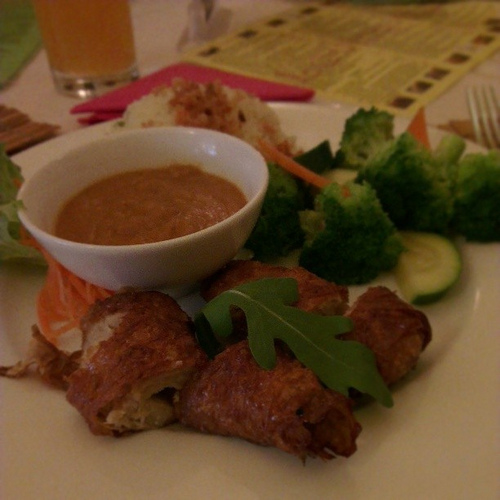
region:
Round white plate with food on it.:
[22, 77, 493, 496]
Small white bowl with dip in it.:
[23, 113, 284, 293]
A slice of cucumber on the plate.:
[371, 213, 466, 310]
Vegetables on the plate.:
[259, 120, 495, 300]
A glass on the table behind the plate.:
[7, 0, 147, 99]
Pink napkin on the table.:
[47, 56, 330, 109]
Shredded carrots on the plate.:
[21, 250, 127, 335]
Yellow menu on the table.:
[178, 2, 498, 109]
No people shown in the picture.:
[0, 0, 494, 490]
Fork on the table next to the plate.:
[455, 76, 497, 139]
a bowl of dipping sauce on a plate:
[15, 122, 265, 287]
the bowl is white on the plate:
[15, 120, 270, 290]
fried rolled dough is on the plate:
[6, 280, 426, 455]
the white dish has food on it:
[0, 95, 487, 486]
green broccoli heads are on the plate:
[270, 107, 496, 273]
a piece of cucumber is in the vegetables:
[400, 228, 461, 298]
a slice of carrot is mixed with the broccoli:
[255, 136, 396, 254]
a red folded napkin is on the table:
[68, 55, 313, 113]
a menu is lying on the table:
[181, 3, 492, 111]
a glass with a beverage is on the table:
[32, 5, 142, 97]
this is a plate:
[127, 446, 247, 491]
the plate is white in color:
[442, 324, 473, 378]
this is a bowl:
[21, 127, 261, 288]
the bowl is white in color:
[102, 249, 191, 286]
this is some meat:
[91, 278, 386, 443]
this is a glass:
[38, 3, 138, 89]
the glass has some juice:
[37, 3, 145, 68]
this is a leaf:
[238, 287, 323, 353]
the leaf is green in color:
[247, 295, 277, 321]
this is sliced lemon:
[408, 239, 454, 297]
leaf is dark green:
[181, 270, 409, 427]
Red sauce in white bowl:
[51, 112, 259, 302]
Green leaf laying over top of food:
[206, 275, 378, 419]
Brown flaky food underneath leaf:
[111, 316, 340, 498]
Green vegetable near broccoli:
[391, 192, 467, 331]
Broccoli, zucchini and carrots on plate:
[280, 112, 471, 263]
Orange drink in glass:
[40, 43, 193, 101]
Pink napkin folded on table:
[94, 50, 370, 140]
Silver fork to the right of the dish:
[456, 67, 491, 118]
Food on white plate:
[261, 68, 396, 202]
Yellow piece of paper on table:
[213, 10, 465, 97]